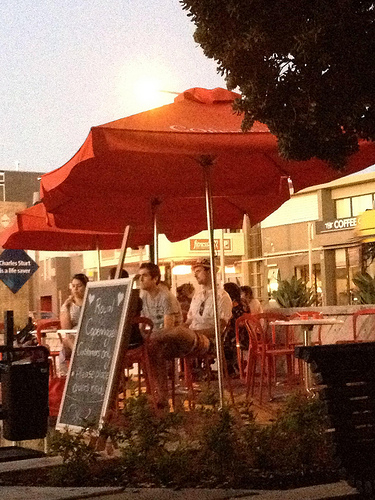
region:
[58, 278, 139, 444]
a chalkboard with writing on it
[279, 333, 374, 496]
the back of a bench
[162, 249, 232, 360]
a man sitting on a stool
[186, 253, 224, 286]
a man wearing a hat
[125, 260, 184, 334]
a man wearing a gray shirt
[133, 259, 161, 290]
the head of a man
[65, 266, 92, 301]
the head of a woman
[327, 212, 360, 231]
the word coffee on the side of a building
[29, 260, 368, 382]
outdoor seating with people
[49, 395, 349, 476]
plants on the ground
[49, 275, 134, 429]
board with information on it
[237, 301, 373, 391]
table and set of chairs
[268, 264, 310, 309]
plant behind the wall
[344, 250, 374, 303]
plant behind the wall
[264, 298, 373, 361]
wall next to seating area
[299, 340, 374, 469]
bench near seating area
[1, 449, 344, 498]
concrete circling plant area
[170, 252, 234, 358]
man with hat seated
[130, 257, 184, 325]
man in gray t-shirt leaning forward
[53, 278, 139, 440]
small chalkboard with restaurant menu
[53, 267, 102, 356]
woman with dark hair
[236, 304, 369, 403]
empty table in restaurant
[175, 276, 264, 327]
group of people in background at restaurant table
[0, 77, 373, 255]
large red umbrellas covering restaurant tables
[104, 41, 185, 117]
yellow glare from the sun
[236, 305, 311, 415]
red chair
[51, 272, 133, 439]
Menu written on a chalkboard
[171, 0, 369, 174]
Green leaves on a tree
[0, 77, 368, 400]
Red and big umbrellas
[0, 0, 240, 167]
The sky appears overcast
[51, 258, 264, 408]
People are sitting on chairs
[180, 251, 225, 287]
Hat on a man's head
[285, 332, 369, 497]
The side of a black bench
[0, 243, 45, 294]
White writing on a sign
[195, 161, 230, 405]
The silver stand of an umbrella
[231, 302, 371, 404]
Red chairs around a table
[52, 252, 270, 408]
Friends having dinner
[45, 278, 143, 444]
The specials of the day.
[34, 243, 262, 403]
Friends listening intently to a speaker.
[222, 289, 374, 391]
Empty table for patrons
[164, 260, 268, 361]
Women having dinner.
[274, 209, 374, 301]
A coffee shop.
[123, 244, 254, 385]
Two men fighting silently.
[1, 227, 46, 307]
A promotional sign hanging from the canopy.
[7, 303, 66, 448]
A garbage can filled with trash from the city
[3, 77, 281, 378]
Restaurant patrons enjoying outdoor dining.